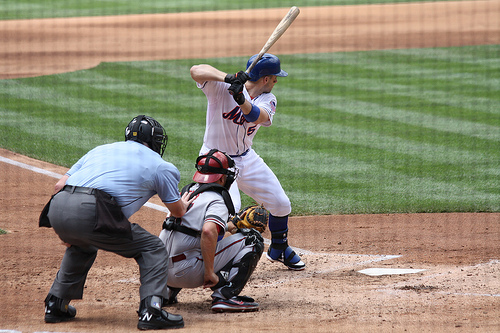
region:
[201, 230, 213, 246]
part of an elbow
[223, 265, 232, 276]
edge of a shoe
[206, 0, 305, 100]
a wooden bat in hand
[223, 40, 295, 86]
a blue hat on head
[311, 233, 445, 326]
home plate in the dirt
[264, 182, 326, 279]
a blue sock on leg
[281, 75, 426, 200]
the lush green grass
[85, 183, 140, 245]
a black bag on a belt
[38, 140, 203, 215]
a blue short sleeve shirt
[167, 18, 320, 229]
a baseball player in uniform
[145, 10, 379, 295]
this is a baseball player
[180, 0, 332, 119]
man holding a baseball bat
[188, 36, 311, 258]
man wearing a white uniform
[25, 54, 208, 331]
this is an umpire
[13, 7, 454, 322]
people playing a baseball game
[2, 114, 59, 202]
white line on ground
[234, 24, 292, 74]
batter has blue helmet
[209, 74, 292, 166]
white and blue shirt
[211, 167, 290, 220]
batter has white pants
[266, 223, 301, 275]
batter has blue shoes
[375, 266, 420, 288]
home plate is white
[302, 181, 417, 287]
dirt on field is brown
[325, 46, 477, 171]
green grass in infield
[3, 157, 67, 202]
foul line is white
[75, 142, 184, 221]
umpire has blue shirt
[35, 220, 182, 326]
umpire has grey pants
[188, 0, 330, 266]
a man getting ready to swing a baseball bat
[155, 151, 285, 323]
a base ball catcher squatted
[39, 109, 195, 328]
an umpire making calls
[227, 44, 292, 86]
a blue base ball helmet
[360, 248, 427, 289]
a white home base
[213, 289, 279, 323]
a black baseball cleat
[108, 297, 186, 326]
a new balance umpire shoe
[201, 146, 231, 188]
a red baseball helmet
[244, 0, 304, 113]
a wooden base ball bat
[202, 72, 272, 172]
a mets jersey